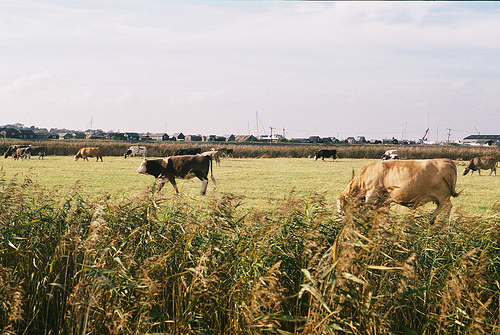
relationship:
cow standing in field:
[331, 156, 468, 225] [0, 153, 499, 330]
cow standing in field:
[133, 155, 216, 196] [0, 153, 499, 330]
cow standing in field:
[73, 146, 104, 162] [0, 153, 499, 330]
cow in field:
[133, 155, 216, 196] [1, 155, 497, 275]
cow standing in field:
[460, 156, 497, 178] [0, 153, 499, 330]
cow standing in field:
[164, 143, 248, 184] [9, 157, 484, 290]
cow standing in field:
[133, 155, 216, 196] [7, 144, 484, 257]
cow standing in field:
[78, 151, 109, 164] [15, 168, 470, 304]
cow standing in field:
[133, 155, 216, 196] [15, 168, 470, 304]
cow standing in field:
[466, 148, 495, 177] [15, 168, 470, 304]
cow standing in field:
[305, 142, 343, 162] [15, 168, 470, 304]